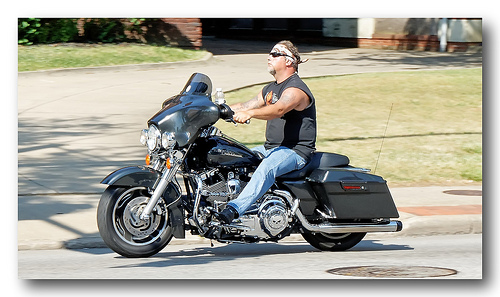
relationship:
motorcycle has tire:
[128, 114, 379, 243] [101, 191, 113, 216]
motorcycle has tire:
[128, 114, 379, 243] [315, 239, 344, 247]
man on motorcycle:
[250, 51, 312, 154] [128, 114, 379, 243]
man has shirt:
[250, 51, 312, 154] [283, 114, 307, 144]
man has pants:
[250, 51, 312, 154] [275, 155, 298, 169]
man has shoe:
[250, 51, 312, 154] [225, 206, 235, 216]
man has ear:
[250, 51, 312, 154] [286, 57, 294, 65]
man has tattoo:
[250, 51, 312, 154] [284, 93, 292, 103]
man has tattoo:
[250, 51, 312, 154] [244, 103, 257, 108]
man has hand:
[250, 51, 312, 154] [239, 113, 246, 122]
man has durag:
[250, 51, 312, 154] [276, 44, 284, 54]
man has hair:
[250, 51, 312, 154] [283, 38, 294, 48]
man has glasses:
[250, 51, 312, 154] [272, 52, 280, 59]